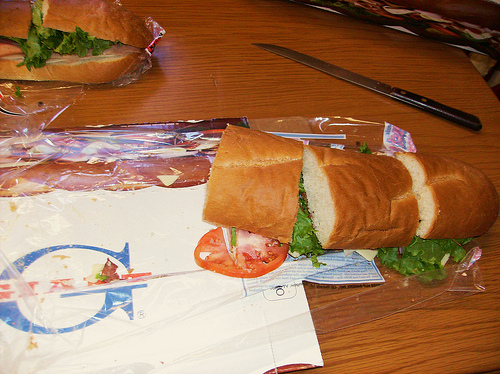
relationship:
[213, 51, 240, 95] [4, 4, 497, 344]
table in photo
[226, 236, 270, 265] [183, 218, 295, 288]
slice of tomato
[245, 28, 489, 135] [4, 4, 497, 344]
knife in photo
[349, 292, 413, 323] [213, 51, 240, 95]
wrapper on table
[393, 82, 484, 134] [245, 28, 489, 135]
handle of knife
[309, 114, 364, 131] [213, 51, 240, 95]
plastic bag on top of table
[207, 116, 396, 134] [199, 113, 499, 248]
plastic wrap under sub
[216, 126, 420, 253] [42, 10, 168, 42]
slices of bread loaf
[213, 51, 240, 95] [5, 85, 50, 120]
table has plastic cover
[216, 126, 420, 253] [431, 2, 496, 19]
three slices of bread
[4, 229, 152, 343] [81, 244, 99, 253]
g written in blue color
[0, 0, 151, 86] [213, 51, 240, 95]
bread loaf on table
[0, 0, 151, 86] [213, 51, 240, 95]
bread loaf on top of table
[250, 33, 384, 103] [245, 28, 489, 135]
blade of knife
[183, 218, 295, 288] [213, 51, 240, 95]
tomato on table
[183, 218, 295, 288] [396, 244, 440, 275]
tomato on top of lettuce